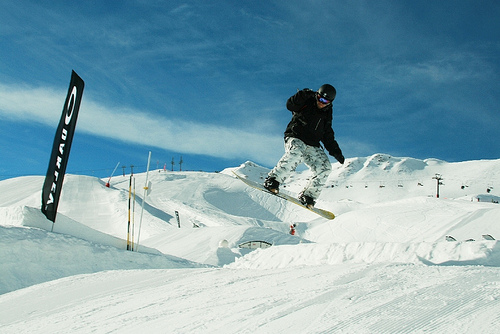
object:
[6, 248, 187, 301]
snow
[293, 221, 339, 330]
ground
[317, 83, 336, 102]
helmet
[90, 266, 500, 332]
tracks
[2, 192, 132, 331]
ground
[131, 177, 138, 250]
pole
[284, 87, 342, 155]
jacket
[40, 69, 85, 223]
banner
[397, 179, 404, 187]
ski lift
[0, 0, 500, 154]
sky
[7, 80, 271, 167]
cloud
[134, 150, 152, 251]
pole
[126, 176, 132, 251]
pole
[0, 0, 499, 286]
scene outside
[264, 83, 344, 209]
man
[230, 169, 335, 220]
snowboard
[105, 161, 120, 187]
poles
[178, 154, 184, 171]
pole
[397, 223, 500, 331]
ground